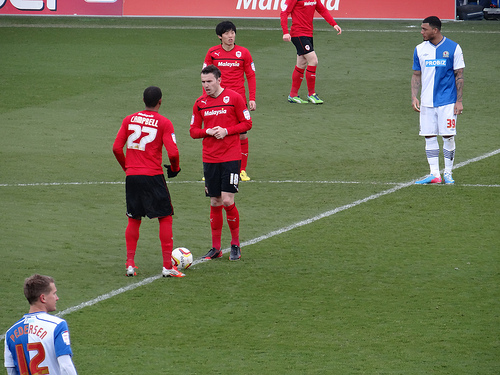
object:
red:
[111, 107, 182, 182]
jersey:
[188, 89, 246, 161]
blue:
[410, 36, 465, 110]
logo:
[424, 58, 451, 71]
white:
[413, 99, 463, 137]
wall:
[3, 0, 456, 24]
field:
[0, 15, 500, 375]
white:
[240, 178, 422, 255]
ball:
[170, 246, 195, 269]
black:
[124, 173, 170, 221]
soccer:
[104, 0, 341, 289]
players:
[403, 17, 465, 186]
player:
[112, 87, 178, 295]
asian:
[196, 15, 257, 113]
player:
[284, 0, 331, 115]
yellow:
[279, 91, 324, 110]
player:
[404, 19, 468, 191]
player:
[7, 267, 88, 374]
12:
[7, 343, 46, 374]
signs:
[3, 0, 126, 17]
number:
[444, 115, 462, 131]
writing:
[420, 58, 452, 70]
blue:
[444, 172, 456, 185]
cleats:
[415, 172, 444, 187]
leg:
[420, 108, 441, 168]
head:
[192, 63, 224, 96]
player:
[182, 66, 246, 258]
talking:
[109, 64, 254, 279]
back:
[114, 109, 171, 182]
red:
[205, 202, 243, 250]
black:
[200, 247, 224, 261]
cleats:
[198, 244, 224, 263]